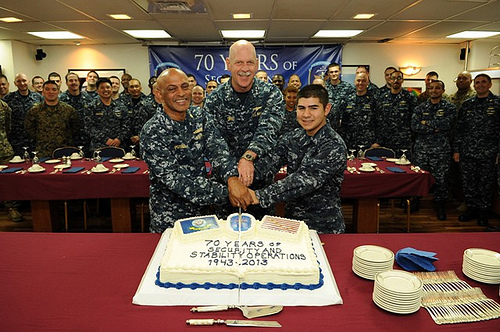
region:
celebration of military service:
[4, 9, 499, 325]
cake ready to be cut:
[142, 200, 332, 317]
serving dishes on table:
[346, 227, 499, 327]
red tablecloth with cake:
[41, 264, 101, 311]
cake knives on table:
[186, 296, 293, 322]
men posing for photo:
[146, 32, 356, 220]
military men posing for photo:
[6, 32, 483, 206]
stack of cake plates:
[368, 264, 422, 318]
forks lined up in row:
[421, 284, 473, 329]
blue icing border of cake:
[260, 280, 300, 292]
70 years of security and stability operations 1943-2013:
[163, 213, 319, 287]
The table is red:
[2, 228, 498, 276]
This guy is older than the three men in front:
[208, 31, 280, 103]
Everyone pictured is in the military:
[1, 56, 499, 123]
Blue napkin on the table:
[391, 229, 451, 279]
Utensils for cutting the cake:
[161, 302, 289, 329]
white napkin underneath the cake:
[129, 201, 356, 314]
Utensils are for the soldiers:
[394, 247, 499, 329]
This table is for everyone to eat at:
[4, 150, 438, 188]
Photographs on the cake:
[162, 199, 308, 241]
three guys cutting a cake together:
[141, 40, 347, 237]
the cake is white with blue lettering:
[158, 209, 326, 292]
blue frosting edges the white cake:
[157, 229, 325, 291]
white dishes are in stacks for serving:
[349, 238, 499, 323]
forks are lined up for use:
[411, 265, 498, 324]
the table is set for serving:
[3, 142, 433, 206]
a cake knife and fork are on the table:
[183, 300, 286, 329]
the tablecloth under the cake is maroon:
[0, 227, 499, 327]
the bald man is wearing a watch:
[240, 147, 257, 165]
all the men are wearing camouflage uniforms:
[1, 39, 496, 226]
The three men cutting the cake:
[142, 38, 349, 238]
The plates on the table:
[348, 242, 499, 316]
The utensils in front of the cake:
[180, 301, 286, 331]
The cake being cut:
[153, 211, 328, 291]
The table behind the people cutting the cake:
[0, 156, 433, 205]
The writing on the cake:
[187, 238, 306, 265]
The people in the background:
[0, 62, 499, 219]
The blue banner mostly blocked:
[144, 38, 344, 103]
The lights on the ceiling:
[0, 10, 498, 45]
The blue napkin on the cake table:
[394, 243, 439, 279]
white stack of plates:
[349, 240, 436, 323]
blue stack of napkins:
[393, 241, 452, 282]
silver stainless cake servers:
[189, 287, 259, 328]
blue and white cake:
[171, 207, 333, 295]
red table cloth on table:
[32, 222, 123, 301]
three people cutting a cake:
[132, 45, 391, 213]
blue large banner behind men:
[158, 47, 342, 82]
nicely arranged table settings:
[23, 158, 146, 175]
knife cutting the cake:
[221, 203, 273, 249]